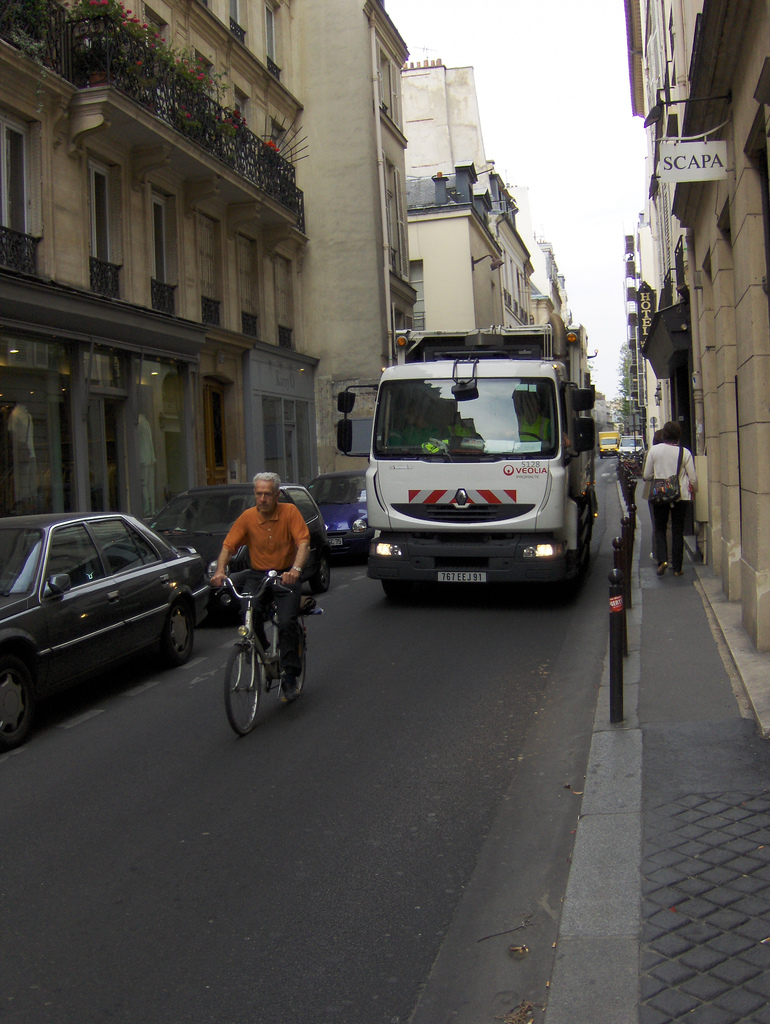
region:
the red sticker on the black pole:
[609, 591, 627, 613]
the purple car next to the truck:
[306, 469, 373, 560]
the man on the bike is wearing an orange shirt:
[207, 469, 309, 703]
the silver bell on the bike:
[264, 569, 286, 583]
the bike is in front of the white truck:
[211, 569, 323, 738]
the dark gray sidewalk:
[639, 726, 765, 1021]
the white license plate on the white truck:
[432, 571, 491, 584]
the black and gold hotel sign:
[638, 289, 653, 351]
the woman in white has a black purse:
[645, 442, 684, 505]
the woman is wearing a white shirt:
[642, 418, 698, 578]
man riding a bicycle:
[217, 474, 312, 733]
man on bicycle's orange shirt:
[228, 507, 307, 574]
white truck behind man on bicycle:
[339, 329, 596, 597]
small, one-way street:
[4, 453, 612, 1021]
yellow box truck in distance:
[599, 431, 619, 455]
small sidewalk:
[631, 467, 768, 1021]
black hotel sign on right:
[638, 278, 655, 339]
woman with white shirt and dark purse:
[642, 418, 697, 576]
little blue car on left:
[309, 472, 372, 555]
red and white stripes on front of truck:
[409, 488, 515, 505]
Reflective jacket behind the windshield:
[423, 436, 447, 454]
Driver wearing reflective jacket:
[512, 389, 551, 440]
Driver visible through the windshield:
[507, 392, 553, 444]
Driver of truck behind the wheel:
[508, 391, 552, 441]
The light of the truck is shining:
[376, 542, 390, 556]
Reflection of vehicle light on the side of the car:
[78, 609, 87, 617]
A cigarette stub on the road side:
[545, 977, 551, 986]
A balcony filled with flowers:
[88, 28, 152, 77]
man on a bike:
[175, 443, 344, 664]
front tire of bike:
[174, 637, 303, 748]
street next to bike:
[308, 694, 484, 856]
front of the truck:
[314, 335, 614, 627]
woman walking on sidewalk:
[597, 375, 749, 587]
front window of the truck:
[310, 349, 605, 485]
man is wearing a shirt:
[231, 485, 297, 588]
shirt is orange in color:
[228, 509, 302, 577]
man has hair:
[253, 463, 286, 491]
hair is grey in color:
[248, 452, 287, 491]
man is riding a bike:
[195, 439, 313, 711]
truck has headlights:
[521, 531, 571, 572]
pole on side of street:
[585, 549, 659, 749]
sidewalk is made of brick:
[646, 520, 758, 982]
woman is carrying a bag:
[638, 430, 671, 511]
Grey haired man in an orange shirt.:
[209, 470, 312, 693]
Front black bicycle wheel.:
[221, 642, 265, 735]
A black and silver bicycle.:
[206, 560, 324, 732]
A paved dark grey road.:
[6, 451, 616, 1020]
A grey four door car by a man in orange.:
[1, 513, 212, 753]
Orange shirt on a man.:
[220, 504, 312, 573]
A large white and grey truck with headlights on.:
[335, 323, 597, 600]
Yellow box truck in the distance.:
[596, 427, 622, 457]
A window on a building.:
[237, 224, 265, 342]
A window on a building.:
[272, 257, 299, 349]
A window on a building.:
[151, 190, 185, 304]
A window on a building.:
[83, 157, 117, 296]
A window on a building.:
[0, 129, 46, 268]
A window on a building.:
[497, 250, 510, 302]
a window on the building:
[123, 188, 171, 298]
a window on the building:
[200, 221, 228, 300]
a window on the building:
[226, 239, 250, 302]